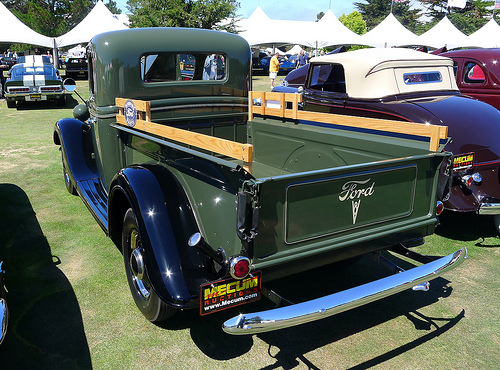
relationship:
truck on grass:
[46, 17, 467, 328] [3, 102, 492, 362]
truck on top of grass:
[46, 17, 467, 328] [3, 102, 492, 362]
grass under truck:
[3, 102, 492, 362] [46, 17, 467, 328]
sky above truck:
[16, 2, 492, 40] [46, 17, 467, 328]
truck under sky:
[46, 17, 467, 328] [16, 2, 492, 40]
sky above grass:
[16, 2, 492, 40] [3, 102, 492, 362]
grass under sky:
[3, 102, 492, 362] [16, 2, 492, 40]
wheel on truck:
[116, 202, 181, 329] [46, 17, 467, 328]